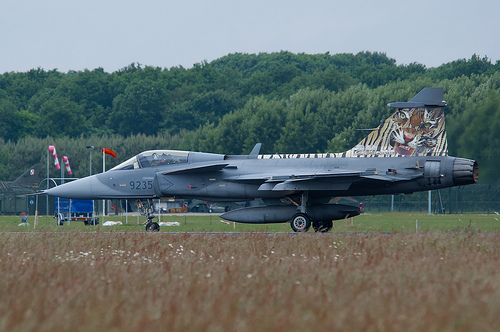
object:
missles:
[223, 199, 383, 239]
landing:
[139, 196, 165, 235]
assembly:
[133, 196, 157, 227]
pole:
[44, 149, 52, 218]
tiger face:
[383, 107, 447, 157]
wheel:
[143, 222, 161, 233]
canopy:
[136, 149, 190, 168]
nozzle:
[451, 158, 483, 184]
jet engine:
[358, 151, 481, 198]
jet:
[38, 86, 482, 234]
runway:
[0, 228, 487, 238]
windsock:
[102, 147, 116, 158]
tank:
[217, 204, 362, 224]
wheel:
[288, 213, 311, 234]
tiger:
[384, 107, 441, 158]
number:
[146, 178, 154, 191]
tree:
[0, 49, 499, 214]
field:
[0, 211, 498, 331]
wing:
[220, 164, 436, 191]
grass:
[0, 213, 499, 331]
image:
[351, 106, 446, 157]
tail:
[348, 86, 450, 158]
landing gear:
[289, 190, 335, 235]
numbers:
[129, 180, 136, 192]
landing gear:
[137, 198, 162, 232]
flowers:
[243, 272, 256, 279]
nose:
[42, 171, 103, 203]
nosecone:
[41, 176, 96, 205]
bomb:
[216, 201, 362, 225]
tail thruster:
[452, 157, 480, 186]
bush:
[0, 225, 499, 332]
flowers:
[266, 247, 276, 254]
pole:
[100, 153, 108, 218]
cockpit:
[106, 148, 186, 171]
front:
[39, 149, 189, 226]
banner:
[61, 155, 74, 177]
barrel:
[179, 204, 189, 213]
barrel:
[170, 205, 178, 213]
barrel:
[166, 207, 171, 214]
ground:
[0, 209, 500, 331]